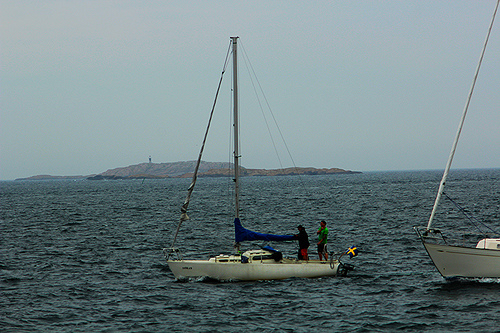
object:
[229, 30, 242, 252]
mast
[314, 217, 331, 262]
man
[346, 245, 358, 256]
orange x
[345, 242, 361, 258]
flag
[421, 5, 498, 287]
boat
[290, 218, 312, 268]
man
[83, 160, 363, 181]
island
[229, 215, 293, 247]
flag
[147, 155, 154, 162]
lighthouse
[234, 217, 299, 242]
sail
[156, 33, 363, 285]
boat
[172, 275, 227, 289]
wave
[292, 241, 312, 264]
something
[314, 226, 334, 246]
green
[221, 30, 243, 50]
top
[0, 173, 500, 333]
water